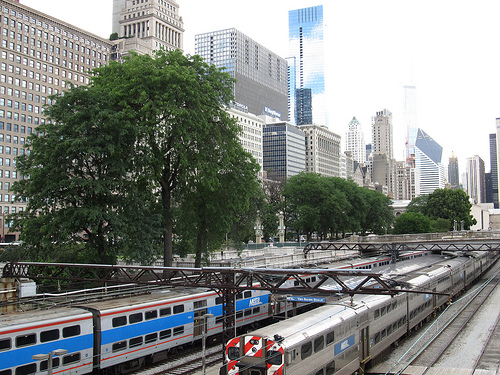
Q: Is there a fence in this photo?
A: No, there are no fences.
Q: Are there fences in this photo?
A: No, there are no fences.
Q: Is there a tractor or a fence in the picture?
A: No, there are no fences or tractors.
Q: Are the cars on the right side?
A: No, the cars are on the left of the image.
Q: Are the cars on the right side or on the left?
A: The cars are on the left of the image.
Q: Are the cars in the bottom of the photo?
A: Yes, the cars are in the bottom of the image.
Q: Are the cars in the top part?
A: No, the cars are in the bottom of the image.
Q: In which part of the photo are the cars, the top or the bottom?
A: The cars are in the bottom of the image.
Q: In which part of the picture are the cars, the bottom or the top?
A: The cars are in the bottom of the image.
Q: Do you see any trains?
A: Yes, there are trains.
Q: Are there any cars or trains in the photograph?
A: Yes, there are trains.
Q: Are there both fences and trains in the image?
A: No, there are trains but no fences.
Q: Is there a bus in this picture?
A: No, there are no buses.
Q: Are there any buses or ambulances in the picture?
A: No, there are no buses or ambulances.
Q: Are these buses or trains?
A: These are trains.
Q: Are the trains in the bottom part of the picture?
A: Yes, the trains are in the bottom of the image.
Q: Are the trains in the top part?
A: No, the trains are in the bottom of the image.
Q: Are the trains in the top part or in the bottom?
A: The trains are in the bottom of the image.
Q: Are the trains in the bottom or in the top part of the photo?
A: The trains are in the bottom of the image.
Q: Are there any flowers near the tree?
A: No, there are trains near the tree.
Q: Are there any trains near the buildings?
A: Yes, there are trains near the buildings.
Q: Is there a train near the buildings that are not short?
A: Yes, there are trains near the buildings.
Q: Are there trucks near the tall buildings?
A: No, there are trains near the buildings.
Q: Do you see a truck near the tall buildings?
A: No, there are trains near the buildings.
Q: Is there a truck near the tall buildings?
A: No, there are trains near the buildings.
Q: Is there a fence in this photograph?
A: No, there are no fences.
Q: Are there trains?
A: Yes, there is a train.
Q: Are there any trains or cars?
A: Yes, there is a train.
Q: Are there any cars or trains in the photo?
A: Yes, there is a train.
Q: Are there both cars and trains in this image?
A: Yes, there are both a train and a car.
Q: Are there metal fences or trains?
A: Yes, there is a metal train.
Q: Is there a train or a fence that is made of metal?
A: Yes, the train is made of metal.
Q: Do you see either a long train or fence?
A: Yes, there is a long train.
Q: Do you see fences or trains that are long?
A: Yes, the train is long.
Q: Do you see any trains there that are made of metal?
A: Yes, there is a train that is made of metal.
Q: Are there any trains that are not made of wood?
A: Yes, there is a train that is made of metal.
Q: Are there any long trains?
A: Yes, there is a long train.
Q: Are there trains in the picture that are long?
A: Yes, there is a train that is long.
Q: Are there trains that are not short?
A: Yes, there is a long train.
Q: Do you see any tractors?
A: No, there are no tractors.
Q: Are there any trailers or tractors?
A: No, there are no tractors or trailers.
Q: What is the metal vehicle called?
A: The vehicle is a train.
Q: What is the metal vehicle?
A: The vehicle is a train.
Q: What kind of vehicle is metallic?
A: The vehicle is a train.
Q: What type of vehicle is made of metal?
A: The vehicle is a train.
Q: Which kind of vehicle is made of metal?
A: The vehicle is a train.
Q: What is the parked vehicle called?
A: The vehicle is a train.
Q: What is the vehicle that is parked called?
A: The vehicle is a train.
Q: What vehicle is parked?
A: The vehicle is a train.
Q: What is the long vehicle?
A: The vehicle is a train.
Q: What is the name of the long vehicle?
A: The vehicle is a train.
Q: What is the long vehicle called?
A: The vehicle is a train.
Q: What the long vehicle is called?
A: The vehicle is a train.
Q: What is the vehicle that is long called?
A: The vehicle is a train.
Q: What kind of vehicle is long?
A: The vehicle is a train.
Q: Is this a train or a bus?
A: This is a train.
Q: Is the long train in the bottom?
A: Yes, the train is in the bottom of the image.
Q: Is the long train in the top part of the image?
A: No, the train is in the bottom of the image.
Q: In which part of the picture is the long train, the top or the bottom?
A: The train is in the bottom of the image.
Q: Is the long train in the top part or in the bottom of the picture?
A: The train is in the bottom of the image.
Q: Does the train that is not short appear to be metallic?
A: Yes, the train is metallic.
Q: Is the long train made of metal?
A: Yes, the train is made of metal.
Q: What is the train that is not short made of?
A: The train is made of metal.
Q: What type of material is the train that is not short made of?
A: The train is made of metal.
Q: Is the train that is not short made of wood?
A: No, the train is made of metal.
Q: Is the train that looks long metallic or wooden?
A: The train is metallic.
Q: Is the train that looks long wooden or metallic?
A: The train is metallic.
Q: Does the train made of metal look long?
A: Yes, the train is long.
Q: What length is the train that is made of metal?
A: The train is long.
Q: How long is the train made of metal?
A: The train is long.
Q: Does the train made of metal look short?
A: No, the train is long.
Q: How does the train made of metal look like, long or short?
A: The train is long.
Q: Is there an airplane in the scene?
A: No, there are no airplanes.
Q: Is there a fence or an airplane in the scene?
A: No, there are no airplanes or fences.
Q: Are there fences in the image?
A: No, there are no fences.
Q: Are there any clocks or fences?
A: No, there are no fences or clocks.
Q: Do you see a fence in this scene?
A: No, there are no fences.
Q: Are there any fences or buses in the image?
A: No, there are no fences or buses.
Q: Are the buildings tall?
A: Yes, the buildings are tall.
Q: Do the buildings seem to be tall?
A: Yes, the buildings are tall.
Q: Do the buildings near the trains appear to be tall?
A: Yes, the buildings are tall.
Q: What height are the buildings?
A: The buildings are tall.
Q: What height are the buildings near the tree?
A: The buildings are tall.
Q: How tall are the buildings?
A: The buildings are tall.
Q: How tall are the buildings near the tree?
A: The buildings are tall.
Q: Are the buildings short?
A: No, the buildings are tall.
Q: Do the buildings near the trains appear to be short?
A: No, the buildings are tall.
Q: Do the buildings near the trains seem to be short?
A: No, the buildings are tall.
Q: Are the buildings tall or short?
A: The buildings are tall.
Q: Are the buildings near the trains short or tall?
A: The buildings are tall.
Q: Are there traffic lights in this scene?
A: No, there are no traffic lights.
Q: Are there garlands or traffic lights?
A: No, there are no traffic lights or garlands.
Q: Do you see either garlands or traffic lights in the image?
A: No, there are no traffic lights or garlands.